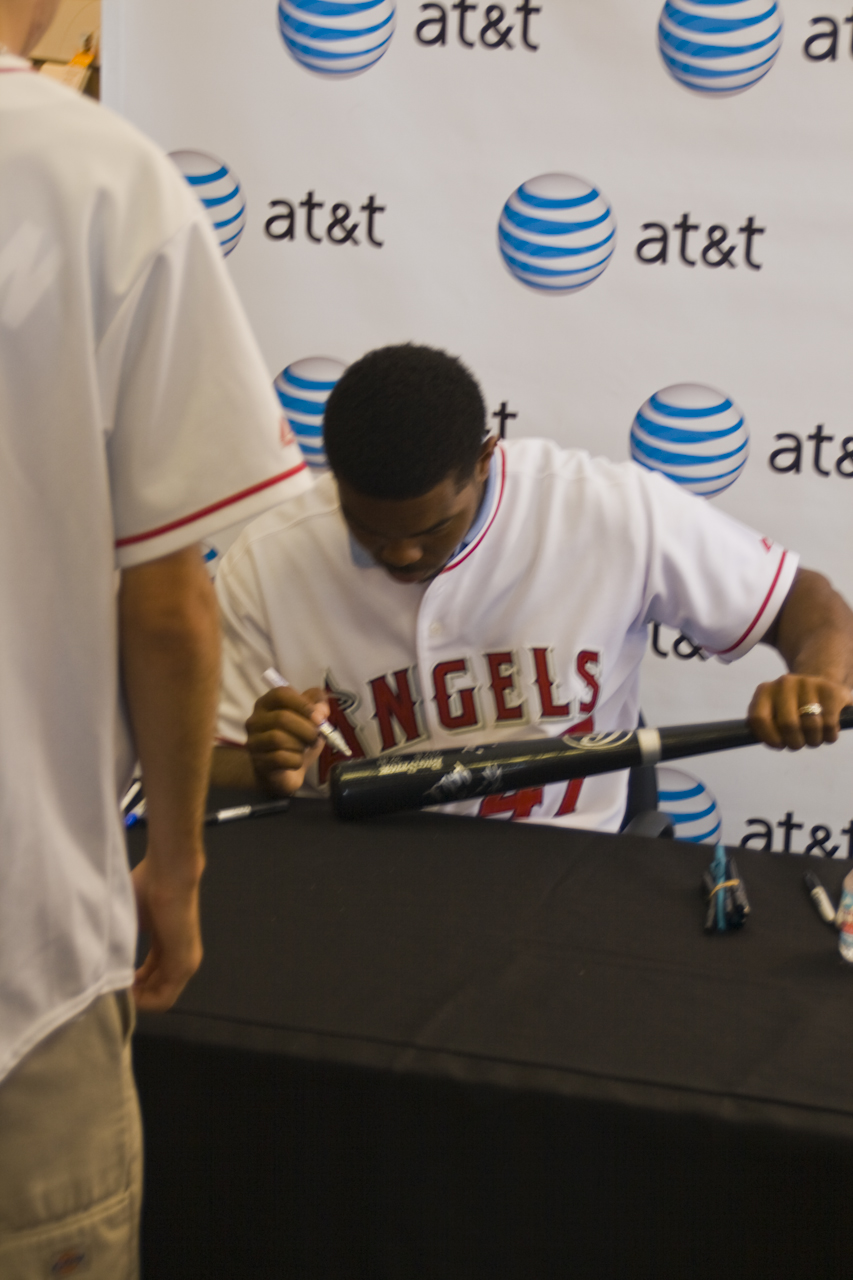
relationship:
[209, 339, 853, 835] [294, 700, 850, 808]
man signing bat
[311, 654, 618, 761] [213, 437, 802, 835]
angels on jersey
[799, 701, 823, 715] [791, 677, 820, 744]
ring around finger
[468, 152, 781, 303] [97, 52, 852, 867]
advertisement on wall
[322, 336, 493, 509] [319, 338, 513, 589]
hair on head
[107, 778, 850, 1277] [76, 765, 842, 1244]
cloth on table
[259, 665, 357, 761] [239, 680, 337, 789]
marker in hand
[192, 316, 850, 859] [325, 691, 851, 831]
man holding bat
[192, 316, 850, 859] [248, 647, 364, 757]
man holding pen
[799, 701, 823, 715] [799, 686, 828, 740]
ring on finger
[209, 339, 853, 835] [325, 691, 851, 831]
man signing bat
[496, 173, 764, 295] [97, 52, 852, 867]
advertisement on wall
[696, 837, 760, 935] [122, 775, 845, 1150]
pens on table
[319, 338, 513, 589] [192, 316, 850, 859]
head of man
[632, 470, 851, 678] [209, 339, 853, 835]
arm of man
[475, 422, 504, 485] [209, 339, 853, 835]
ear of man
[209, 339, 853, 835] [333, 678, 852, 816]
man signing bat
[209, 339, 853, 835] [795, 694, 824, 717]
man wearing ring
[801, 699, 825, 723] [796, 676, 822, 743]
ring on finger